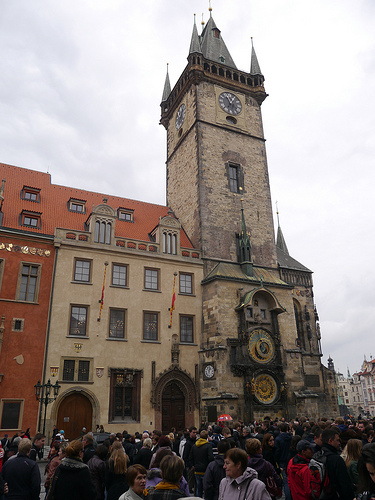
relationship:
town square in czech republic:
[2, 418, 373, 498] [0, 1, 375, 498]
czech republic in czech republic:
[0, 1, 375, 498] [1, 1, 372, 497]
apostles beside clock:
[236, 326, 280, 344] [199, 360, 219, 381]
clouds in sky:
[35, 48, 141, 150] [17, 25, 136, 168]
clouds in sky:
[280, 19, 374, 169] [0, 0, 373, 377]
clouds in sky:
[61, 1, 173, 128] [0, 0, 346, 171]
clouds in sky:
[0, 1, 373, 378] [0, 0, 373, 377]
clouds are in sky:
[35, 48, 141, 150] [22, 31, 373, 203]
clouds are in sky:
[280, 19, 374, 169] [268, 9, 360, 260]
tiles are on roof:
[41, 185, 65, 227] [0, 161, 198, 259]